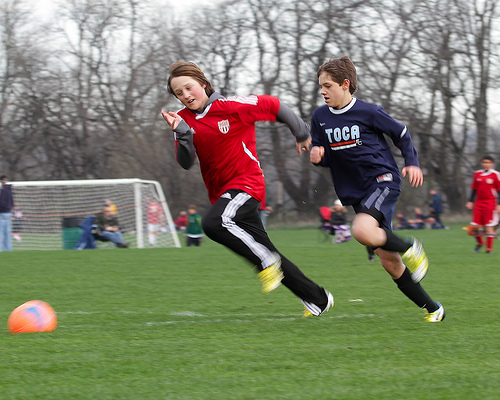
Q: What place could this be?
A: It is a field.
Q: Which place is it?
A: It is a field.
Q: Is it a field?
A: Yes, it is a field.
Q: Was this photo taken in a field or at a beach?
A: It was taken at a field.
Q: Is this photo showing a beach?
A: No, the picture is showing a field.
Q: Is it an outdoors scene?
A: Yes, it is outdoors.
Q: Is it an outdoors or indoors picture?
A: It is outdoors.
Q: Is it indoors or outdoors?
A: It is outdoors.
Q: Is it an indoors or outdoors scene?
A: It is outdoors.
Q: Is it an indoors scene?
A: No, it is outdoors.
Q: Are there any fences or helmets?
A: No, there are no fences or helmets.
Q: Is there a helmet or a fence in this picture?
A: No, there are no fences or helmets.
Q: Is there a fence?
A: No, there are no fences.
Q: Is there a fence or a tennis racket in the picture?
A: No, there are no fences or rackets.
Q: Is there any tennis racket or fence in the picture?
A: No, there are no fences or rackets.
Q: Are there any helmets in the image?
A: No, there are no helmets.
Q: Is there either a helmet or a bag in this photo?
A: No, there are no helmets or bags.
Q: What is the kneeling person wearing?
A: The person is wearing a shirt.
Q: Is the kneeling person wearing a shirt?
A: Yes, the person is wearing a shirt.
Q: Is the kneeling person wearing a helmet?
A: No, the person is wearing a shirt.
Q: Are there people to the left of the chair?
A: Yes, there is a person to the left of the chair.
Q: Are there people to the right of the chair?
A: No, the person is to the left of the chair.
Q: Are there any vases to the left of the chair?
A: No, there is a person to the left of the chair.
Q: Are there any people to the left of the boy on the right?
A: Yes, there is a person to the left of the boy.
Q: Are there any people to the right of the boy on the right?
A: No, the person is to the left of the boy.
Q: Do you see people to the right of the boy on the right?
A: No, the person is to the left of the boy.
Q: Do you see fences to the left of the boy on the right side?
A: No, there is a person to the left of the boy.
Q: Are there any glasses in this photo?
A: No, there are no glasses.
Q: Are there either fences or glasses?
A: No, there are no glasses or fences.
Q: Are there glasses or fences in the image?
A: No, there are no glasses or fences.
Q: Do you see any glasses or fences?
A: No, there are no glasses or fences.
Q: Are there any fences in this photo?
A: No, there are no fences.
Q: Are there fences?
A: No, there are no fences.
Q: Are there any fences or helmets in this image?
A: No, there are no fences or helmets.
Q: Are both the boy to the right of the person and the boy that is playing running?
A: Yes, both the boy and the boy are running.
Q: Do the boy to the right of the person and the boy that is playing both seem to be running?
A: Yes, both the boy and the boy are running.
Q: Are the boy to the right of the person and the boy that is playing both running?
A: Yes, both the boy and the boy are running.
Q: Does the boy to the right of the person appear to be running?
A: Yes, the boy is running.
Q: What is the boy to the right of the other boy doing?
A: The boy is running.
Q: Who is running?
A: The boy is running.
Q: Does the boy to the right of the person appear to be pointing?
A: No, the boy is running.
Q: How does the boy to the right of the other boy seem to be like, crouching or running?
A: The boy is running.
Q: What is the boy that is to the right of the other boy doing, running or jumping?
A: The boy is running.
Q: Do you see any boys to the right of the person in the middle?
A: Yes, there is a boy to the right of the person.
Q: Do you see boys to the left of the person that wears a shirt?
A: No, the boy is to the right of the person.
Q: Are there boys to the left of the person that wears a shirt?
A: No, the boy is to the right of the person.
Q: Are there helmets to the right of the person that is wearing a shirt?
A: No, there is a boy to the right of the person.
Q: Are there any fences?
A: No, there are no fences.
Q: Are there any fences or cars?
A: No, there are no fences or cars.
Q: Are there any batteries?
A: No, there are no batteries.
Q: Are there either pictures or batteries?
A: No, there are no batteries or pictures.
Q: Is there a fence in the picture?
A: No, there are no fences.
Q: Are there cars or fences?
A: No, there are no fences or cars.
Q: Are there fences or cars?
A: No, there are no fences or cars.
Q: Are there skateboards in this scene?
A: No, there are no skateboards.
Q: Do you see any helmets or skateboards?
A: No, there are no skateboards or helmets.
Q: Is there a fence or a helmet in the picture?
A: No, there are no fences or helmets.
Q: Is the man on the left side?
A: Yes, the man is on the left of the image.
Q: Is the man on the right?
A: No, the man is on the left of the image.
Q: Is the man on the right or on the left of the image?
A: The man is on the left of the image.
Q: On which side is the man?
A: The man is on the left of the image.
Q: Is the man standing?
A: Yes, the man is standing.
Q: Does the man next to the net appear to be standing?
A: Yes, the man is standing.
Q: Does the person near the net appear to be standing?
A: Yes, the man is standing.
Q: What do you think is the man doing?
A: The man is standing.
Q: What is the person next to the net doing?
A: The man is standing.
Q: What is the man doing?
A: The man is standing.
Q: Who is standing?
A: The man is standing.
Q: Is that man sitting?
A: No, the man is standing.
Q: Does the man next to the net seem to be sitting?
A: No, the man is standing.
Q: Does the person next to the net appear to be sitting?
A: No, the man is standing.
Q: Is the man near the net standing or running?
A: The man is standing.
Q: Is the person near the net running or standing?
A: The man is standing.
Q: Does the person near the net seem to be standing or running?
A: The man is standing.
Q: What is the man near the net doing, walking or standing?
A: The man is standing.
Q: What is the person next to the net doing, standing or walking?
A: The man is standing.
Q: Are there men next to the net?
A: Yes, there is a man next to the net.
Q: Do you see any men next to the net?
A: Yes, there is a man next to the net.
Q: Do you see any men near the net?
A: Yes, there is a man near the net.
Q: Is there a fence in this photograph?
A: No, there are no fences.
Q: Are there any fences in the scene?
A: No, there are no fences.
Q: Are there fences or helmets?
A: No, there are no fences or helmets.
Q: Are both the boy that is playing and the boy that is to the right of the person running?
A: Yes, both the boy and the boy are running.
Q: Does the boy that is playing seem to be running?
A: Yes, the boy is running.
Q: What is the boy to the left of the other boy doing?
A: The boy is running.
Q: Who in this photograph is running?
A: The boy is running.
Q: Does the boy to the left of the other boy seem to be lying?
A: No, the boy is running.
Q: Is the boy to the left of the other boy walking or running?
A: The boy is running.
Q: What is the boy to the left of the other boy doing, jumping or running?
A: The boy is running.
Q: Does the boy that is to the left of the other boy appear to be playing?
A: Yes, the boy is playing.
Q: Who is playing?
A: The boy is playing.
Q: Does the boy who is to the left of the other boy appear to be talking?
A: No, the boy is playing.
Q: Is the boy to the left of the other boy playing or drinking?
A: The boy is playing.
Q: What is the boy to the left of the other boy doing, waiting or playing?
A: The boy is playing.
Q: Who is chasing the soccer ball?
A: The boy is chasing the soccer ball.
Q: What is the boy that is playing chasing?
A: The boy is chasing the soccer ball.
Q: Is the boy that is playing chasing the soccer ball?
A: Yes, the boy is chasing the soccer ball.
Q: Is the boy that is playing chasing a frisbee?
A: No, the boy is chasing the soccer ball.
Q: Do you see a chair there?
A: Yes, there is a chair.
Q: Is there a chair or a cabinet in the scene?
A: Yes, there is a chair.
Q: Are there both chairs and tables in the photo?
A: No, there is a chair but no tables.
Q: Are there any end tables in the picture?
A: No, there are no end tables.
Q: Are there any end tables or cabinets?
A: No, there are no end tables or cabinets.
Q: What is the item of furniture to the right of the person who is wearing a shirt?
A: The piece of furniture is a chair.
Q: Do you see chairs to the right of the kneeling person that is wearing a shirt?
A: Yes, there is a chair to the right of the person.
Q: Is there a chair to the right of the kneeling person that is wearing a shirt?
A: Yes, there is a chair to the right of the person.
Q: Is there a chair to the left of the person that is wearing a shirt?
A: No, the chair is to the right of the person.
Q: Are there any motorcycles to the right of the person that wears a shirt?
A: No, there is a chair to the right of the person.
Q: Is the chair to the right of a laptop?
A: No, the chair is to the right of a person.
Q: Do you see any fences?
A: No, there are no fences.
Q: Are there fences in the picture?
A: No, there are no fences.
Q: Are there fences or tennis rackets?
A: No, there are no fences or tennis rackets.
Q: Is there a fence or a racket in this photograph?
A: No, there are no fences or rackets.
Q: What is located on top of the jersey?
A: The logo is on top of the jersey.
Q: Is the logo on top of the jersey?
A: Yes, the logo is on top of the jersey.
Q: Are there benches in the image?
A: No, there are no benches.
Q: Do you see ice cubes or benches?
A: No, there are no benches or ice cubes.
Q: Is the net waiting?
A: Yes, the net is waiting.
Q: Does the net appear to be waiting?
A: Yes, the net is waiting.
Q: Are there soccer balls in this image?
A: Yes, there is a soccer ball.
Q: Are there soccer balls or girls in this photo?
A: Yes, there is a soccer ball.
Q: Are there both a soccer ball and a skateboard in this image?
A: No, there is a soccer ball but no skateboards.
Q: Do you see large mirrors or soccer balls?
A: Yes, there is a large soccer ball.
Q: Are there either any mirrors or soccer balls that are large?
A: Yes, the soccer ball is large.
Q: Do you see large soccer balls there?
A: Yes, there is a large soccer ball.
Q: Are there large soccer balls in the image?
A: Yes, there is a large soccer ball.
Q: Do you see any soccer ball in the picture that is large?
A: Yes, there is a soccer ball that is large.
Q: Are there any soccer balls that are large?
A: Yes, there is a soccer ball that is large.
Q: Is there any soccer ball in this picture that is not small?
A: Yes, there is a large soccer ball.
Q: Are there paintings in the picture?
A: No, there are no paintings.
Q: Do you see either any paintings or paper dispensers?
A: No, there are no paintings or paper dispensers.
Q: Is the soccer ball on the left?
A: Yes, the soccer ball is on the left of the image.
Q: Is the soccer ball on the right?
A: No, the soccer ball is on the left of the image.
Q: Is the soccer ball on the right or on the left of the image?
A: The soccer ball is on the left of the image.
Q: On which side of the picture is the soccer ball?
A: The soccer ball is on the left of the image.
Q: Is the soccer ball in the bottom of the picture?
A: Yes, the soccer ball is in the bottom of the image.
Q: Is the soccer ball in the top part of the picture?
A: No, the soccer ball is in the bottom of the image.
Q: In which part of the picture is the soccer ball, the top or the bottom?
A: The soccer ball is in the bottom of the image.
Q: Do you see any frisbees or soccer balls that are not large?
A: No, there is a soccer ball but it is large.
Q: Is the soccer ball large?
A: Yes, the soccer ball is large.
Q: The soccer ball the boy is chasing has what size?
A: The soccer ball is large.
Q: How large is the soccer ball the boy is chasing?
A: The soccer ball is large.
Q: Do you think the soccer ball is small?
A: No, the soccer ball is large.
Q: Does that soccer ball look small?
A: No, the soccer ball is large.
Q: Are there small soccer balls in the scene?
A: No, there is a soccer ball but it is large.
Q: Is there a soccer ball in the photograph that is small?
A: No, there is a soccer ball but it is large.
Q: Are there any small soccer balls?
A: No, there is a soccer ball but it is large.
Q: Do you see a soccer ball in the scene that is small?
A: No, there is a soccer ball but it is large.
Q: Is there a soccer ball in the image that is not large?
A: No, there is a soccer ball but it is large.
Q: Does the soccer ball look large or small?
A: The soccer ball is large.